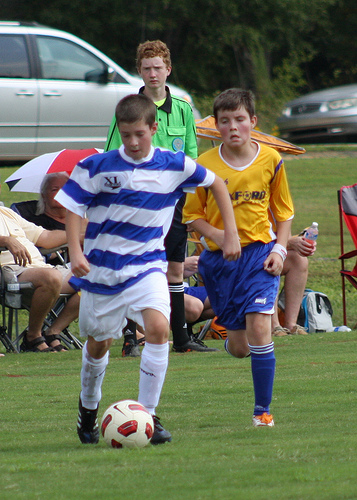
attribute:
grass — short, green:
[1, 140, 356, 499]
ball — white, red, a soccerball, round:
[101, 398, 157, 448]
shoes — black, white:
[77, 395, 170, 449]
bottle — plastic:
[300, 221, 319, 255]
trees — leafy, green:
[1, 1, 356, 96]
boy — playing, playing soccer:
[54, 94, 243, 455]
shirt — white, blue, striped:
[52, 147, 216, 293]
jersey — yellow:
[181, 141, 296, 253]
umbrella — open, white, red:
[5, 148, 104, 193]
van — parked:
[1, 21, 203, 161]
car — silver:
[280, 84, 355, 141]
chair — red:
[338, 180, 357, 333]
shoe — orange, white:
[254, 410, 275, 428]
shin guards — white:
[81, 342, 169, 411]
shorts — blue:
[198, 240, 282, 326]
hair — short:
[116, 95, 156, 130]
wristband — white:
[269, 242, 288, 260]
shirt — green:
[105, 87, 198, 165]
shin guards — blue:
[248, 353, 277, 413]